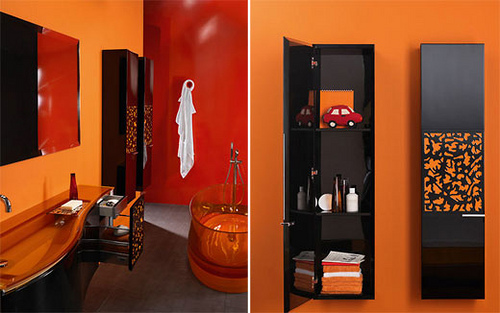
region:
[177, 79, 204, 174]
a white towel on the wall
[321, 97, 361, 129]
a toy car on the shelf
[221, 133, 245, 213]
a chrome faucet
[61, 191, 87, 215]
a large white bar of soap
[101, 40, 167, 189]
a fancy black cabinet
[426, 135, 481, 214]
a wooden pattern on the cabinet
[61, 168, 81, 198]
a red bottle on the tub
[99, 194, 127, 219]
an open drawer next to the tube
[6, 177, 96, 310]
a modern black and yellow tub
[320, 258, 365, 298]
a stack of washcloths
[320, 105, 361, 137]
a toy car on a shelve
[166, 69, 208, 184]
this is a hand towel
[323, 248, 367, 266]
this is a book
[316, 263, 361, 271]
this is a book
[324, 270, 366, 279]
this is a book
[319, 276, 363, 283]
this is a book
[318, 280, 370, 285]
this is a book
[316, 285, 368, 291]
this is a book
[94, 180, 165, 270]
these are drawers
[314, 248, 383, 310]
these are books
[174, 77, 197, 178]
Towel hangs on ring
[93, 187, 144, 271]
Drawer is left open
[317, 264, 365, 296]
Stack of orange and white towels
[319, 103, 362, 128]
Red car on shelf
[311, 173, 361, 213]
Toiletries on shelf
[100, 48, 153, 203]
Modern wall shelving units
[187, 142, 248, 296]
Modern orange glass tub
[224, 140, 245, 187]
Silver tub faucet and sprayer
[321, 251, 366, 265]
Loose papers on shelf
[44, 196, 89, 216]
Soap in dish on counter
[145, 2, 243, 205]
a red wall of room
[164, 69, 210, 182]
a white towel hangs from wall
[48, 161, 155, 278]
drawers are out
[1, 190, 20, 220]
a silver sink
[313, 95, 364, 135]
a red toy car on a shelf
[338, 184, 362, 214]
a white bottle on a shelf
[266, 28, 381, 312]
door of shelf is open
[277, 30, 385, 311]
shelf is color black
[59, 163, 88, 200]
a bottle over the counter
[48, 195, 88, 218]
a white soap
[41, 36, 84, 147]
a mirror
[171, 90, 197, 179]
a white towel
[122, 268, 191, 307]
the floor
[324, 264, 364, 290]
stacked towels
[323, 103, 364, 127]
a small car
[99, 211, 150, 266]
a drawer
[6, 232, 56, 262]
a sink that is orange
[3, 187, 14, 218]
a faucet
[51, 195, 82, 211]
the soap dish is on the sink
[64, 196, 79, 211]
the soap is white